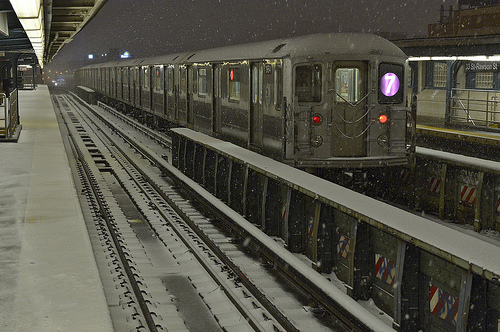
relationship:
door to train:
[332, 60, 371, 157] [74, 30, 418, 169]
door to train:
[250, 60, 267, 150] [74, 30, 418, 169]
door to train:
[212, 62, 225, 136] [74, 30, 418, 169]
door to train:
[164, 64, 169, 125] [74, 30, 418, 169]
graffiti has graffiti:
[439, 288, 461, 323] [439, 288, 461, 323]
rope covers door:
[330, 88, 374, 108] [332, 60, 371, 157]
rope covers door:
[333, 104, 374, 125] [332, 60, 371, 157]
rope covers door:
[334, 119, 372, 138] [332, 60, 371, 157]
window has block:
[432, 59, 452, 87] [434, 71, 440, 77]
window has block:
[473, 69, 494, 90] [477, 74, 480, 80]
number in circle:
[386, 75, 398, 95] [379, 73, 401, 97]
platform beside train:
[0, 82, 116, 330] [74, 30, 418, 169]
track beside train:
[51, 85, 293, 331] [74, 30, 418, 169]